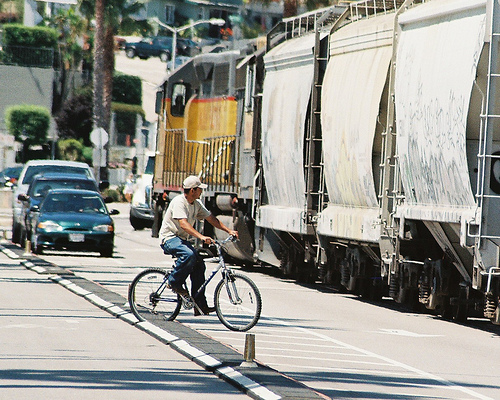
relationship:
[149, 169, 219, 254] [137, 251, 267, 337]
man riding bike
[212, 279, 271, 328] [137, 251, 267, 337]
tire on bike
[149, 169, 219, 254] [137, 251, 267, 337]
man on bike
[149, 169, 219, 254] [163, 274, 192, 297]
man has foot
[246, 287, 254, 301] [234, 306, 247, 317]
reflectors on spike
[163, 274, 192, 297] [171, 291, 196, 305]
foot on pedal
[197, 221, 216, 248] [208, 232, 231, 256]
hand on handle bar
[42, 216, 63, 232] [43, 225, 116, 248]
light on front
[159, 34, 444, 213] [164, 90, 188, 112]
train has driver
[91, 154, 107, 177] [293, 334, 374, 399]
post in road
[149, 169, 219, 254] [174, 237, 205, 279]
man wearing jeans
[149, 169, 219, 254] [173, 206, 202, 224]
man wearing shirt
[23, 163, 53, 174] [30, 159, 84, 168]
front of truck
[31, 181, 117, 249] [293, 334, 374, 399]
car on road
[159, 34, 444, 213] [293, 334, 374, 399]
train on road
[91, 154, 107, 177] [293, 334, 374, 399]
post on road